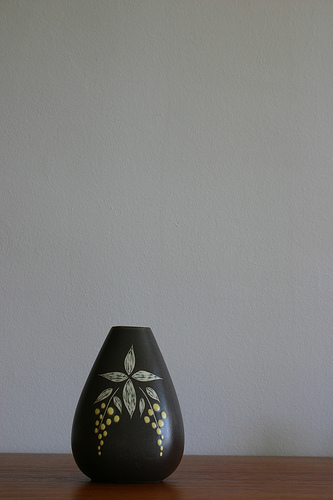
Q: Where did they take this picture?
A: Brown table with a white background.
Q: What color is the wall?
A: White.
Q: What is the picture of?
A: A vase.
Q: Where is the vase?
A: A table.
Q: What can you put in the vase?
A: Flowers.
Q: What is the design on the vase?
A: Grapes.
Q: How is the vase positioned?
A: To the left.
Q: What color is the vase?
A: Brown.